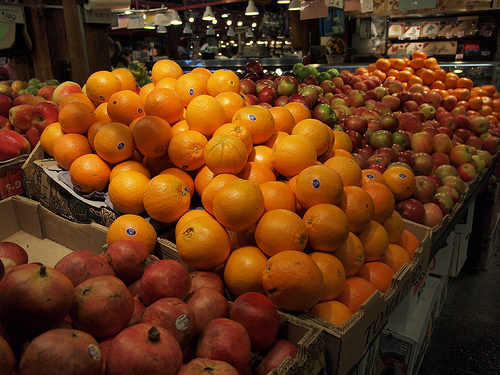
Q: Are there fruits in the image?
A: Yes, there is a fruit.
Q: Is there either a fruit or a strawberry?
A: Yes, there is a fruit.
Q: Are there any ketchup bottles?
A: No, there are no ketchup bottles.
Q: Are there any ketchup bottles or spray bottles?
A: No, there are no ketchup bottles or spray bottles.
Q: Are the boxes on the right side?
A: Yes, the boxes are on the right of the image.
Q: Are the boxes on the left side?
A: No, the boxes are on the right of the image.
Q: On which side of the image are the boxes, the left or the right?
A: The boxes are on the right of the image.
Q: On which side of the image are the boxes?
A: The boxes are on the right of the image.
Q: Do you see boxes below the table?
A: Yes, there are boxes below the table.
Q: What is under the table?
A: The boxes are under the table.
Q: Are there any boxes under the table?
A: Yes, there are boxes under the table.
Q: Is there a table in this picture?
A: Yes, there is a table.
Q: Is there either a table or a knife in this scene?
A: Yes, there is a table.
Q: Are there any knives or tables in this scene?
A: Yes, there is a table.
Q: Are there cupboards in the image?
A: No, there are no cupboards.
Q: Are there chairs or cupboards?
A: No, there are no cupboards or chairs.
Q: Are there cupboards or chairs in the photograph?
A: No, there are no cupboards or chairs.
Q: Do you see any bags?
A: No, there are no bags.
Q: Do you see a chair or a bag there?
A: No, there are no bags or chairs.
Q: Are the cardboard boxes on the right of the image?
A: Yes, the boxes are on the right of the image.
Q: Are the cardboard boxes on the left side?
A: No, the boxes are on the right of the image.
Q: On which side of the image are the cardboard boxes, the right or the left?
A: The boxes are on the right of the image.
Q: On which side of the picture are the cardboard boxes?
A: The boxes are on the right of the image.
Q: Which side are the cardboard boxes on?
A: The boxes are on the right of the image.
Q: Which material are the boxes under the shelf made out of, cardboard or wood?
A: The boxes are made of cardboard.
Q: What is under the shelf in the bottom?
A: The boxes are under the shelf.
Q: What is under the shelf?
A: The boxes are under the shelf.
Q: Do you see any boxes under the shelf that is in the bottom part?
A: Yes, there are boxes under the shelf.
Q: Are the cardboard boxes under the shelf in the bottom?
A: Yes, the boxes are under the shelf.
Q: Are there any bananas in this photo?
A: Yes, there are bananas.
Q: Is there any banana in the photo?
A: Yes, there are bananas.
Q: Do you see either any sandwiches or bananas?
A: Yes, there are bananas.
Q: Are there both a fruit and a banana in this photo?
A: Yes, there are both a banana and a fruit.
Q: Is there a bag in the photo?
A: No, there are no bags.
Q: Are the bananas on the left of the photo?
A: Yes, the bananas are on the left of the image.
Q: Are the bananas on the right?
A: No, the bananas are on the left of the image.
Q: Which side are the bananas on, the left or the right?
A: The bananas are on the left of the image.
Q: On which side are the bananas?
A: The bananas are on the left of the image.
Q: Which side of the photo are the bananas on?
A: The bananas are on the left of the image.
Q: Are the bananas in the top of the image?
A: Yes, the bananas are in the top of the image.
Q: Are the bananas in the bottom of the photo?
A: No, the bananas are in the top of the image.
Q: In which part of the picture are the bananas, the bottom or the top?
A: The bananas are in the top of the image.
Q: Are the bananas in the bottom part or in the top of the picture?
A: The bananas are in the top of the image.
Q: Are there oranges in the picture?
A: Yes, there are oranges.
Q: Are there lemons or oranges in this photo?
A: Yes, there are oranges.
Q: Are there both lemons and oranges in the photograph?
A: No, there are oranges but no lemons.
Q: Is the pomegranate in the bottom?
A: Yes, the pomegranate is in the bottom of the image.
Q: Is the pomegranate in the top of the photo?
A: No, the pomegranate is in the bottom of the image.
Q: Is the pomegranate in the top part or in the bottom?
A: The pomegranate is in the bottom of the image.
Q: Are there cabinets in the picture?
A: No, there are no cabinets.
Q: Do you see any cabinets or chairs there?
A: No, there are no cabinets or chairs.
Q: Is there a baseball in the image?
A: No, there are no baseballs.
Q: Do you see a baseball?
A: No, there are no baseballs.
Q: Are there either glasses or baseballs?
A: No, there are no baseballs or glasses.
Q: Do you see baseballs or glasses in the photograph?
A: No, there are no baseballs or glasses.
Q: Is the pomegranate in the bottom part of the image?
A: Yes, the pomegranate is in the bottom of the image.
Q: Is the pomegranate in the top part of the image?
A: No, the pomegranate is in the bottom of the image.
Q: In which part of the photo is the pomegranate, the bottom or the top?
A: The pomegranate is in the bottom of the image.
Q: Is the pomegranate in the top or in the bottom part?
A: The pomegranate is in the bottom of the image.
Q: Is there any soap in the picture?
A: No, there are no soaps.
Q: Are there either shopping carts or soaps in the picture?
A: No, there are no soaps or shopping carts.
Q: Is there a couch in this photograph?
A: No, there are no couches.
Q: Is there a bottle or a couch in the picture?
A: No, there are no couches or bottles.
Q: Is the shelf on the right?
A: Yes, the shelf is on the right of the image.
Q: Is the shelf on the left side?
A: No, the shelf is on the right of the image.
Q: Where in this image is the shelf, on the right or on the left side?
A: The shelf is on the right of the image.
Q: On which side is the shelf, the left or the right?
A: The shelf is on the right of the image.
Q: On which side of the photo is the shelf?
A: The shelf is on the right of the image.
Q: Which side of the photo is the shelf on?
A: The shelf is on the right of the image.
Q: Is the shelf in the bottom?
A: Yes, the shelf is in the bottom of the image.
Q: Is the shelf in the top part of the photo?
A: No, the shelf is in the bottom of the image.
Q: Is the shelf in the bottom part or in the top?
A: The shelf is in the bottom of the image.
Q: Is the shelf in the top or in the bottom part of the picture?
A: The shelf is in the bottom of the image.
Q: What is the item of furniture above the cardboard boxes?
A: The piece of furniture is a shelf.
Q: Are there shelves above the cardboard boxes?
A: Yes, there is a shelf above the boxes.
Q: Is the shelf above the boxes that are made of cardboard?
A: Yes, the shelf is above the boxes.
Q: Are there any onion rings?
A: No, there are no onion rings.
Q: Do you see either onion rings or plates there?
A: No, there are no onion rings or plates.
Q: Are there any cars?
A: No, there are no cars.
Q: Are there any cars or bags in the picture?
A: No, there are no cars or bags.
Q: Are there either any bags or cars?
A: No, there are no cars or bags.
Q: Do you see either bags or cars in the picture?
A: No, there are no cars or bags.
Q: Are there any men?
A: No, there are no men.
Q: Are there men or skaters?
A: No, there are no men or skaters.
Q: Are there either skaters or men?
A: No, there are no men or skaters.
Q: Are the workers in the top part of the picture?
A: Yes, the workers are in the top of the image.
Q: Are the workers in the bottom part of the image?
A: No, the workers are in the top of the image.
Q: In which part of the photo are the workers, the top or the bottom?
A: The workers are in the top of the image.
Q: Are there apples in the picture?
A: Yes, there are apples.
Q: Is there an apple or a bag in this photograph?
A: Yes, there are apples.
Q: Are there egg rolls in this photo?
A: No, there are no egg rolls.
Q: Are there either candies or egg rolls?
A: No, there are no egg rolls or candies.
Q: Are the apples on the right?
A: Yes, the apples are on the right of the image.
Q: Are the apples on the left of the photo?
A: No, the apples are on the right of the image.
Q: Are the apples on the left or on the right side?
A: The apples are on the right of the image.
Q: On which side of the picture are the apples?
A: The apples are on the right of the image.